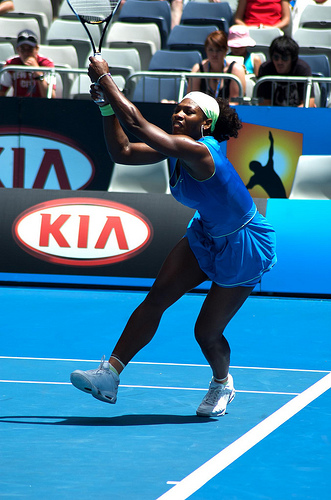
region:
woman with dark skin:
[61, 37, 292, 441]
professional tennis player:
[70, 41, 281, 432]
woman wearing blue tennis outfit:
[65, 44, 295, 444]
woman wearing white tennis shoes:
[60, 49, 282, 421]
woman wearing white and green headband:
[55, 29, 274, 445]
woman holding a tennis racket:
[59, 20, 271, 425]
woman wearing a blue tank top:
[66, 38, 280, 423]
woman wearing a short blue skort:
[55, 50, 283, 427]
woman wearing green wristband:
[68, 39, 285, 432]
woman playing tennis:
[47, 42, 293, 446]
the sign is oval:
[11, 195, 157, 268]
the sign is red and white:
[8, 194, 154, 269]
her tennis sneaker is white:
[71, 362, 124, 405]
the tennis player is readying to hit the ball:
[49, 0, 284, 426]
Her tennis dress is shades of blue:
[140, 134, 291, 300]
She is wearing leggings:
[102, 228, 252, 379]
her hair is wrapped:
[178, 85, 226, 137]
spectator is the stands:
[186, 29, 245, 103]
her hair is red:
[202, 29, 231, 64]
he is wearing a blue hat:
[15, 29, 39, 54]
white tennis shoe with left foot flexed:
[61, 351, 170, 431]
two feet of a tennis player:
[46, 343, 249, 422]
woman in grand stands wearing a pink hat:
[229, 25, 256, 97]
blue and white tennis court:
[0, 109, 299, 479]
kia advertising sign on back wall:
[2, 186, 329, 266]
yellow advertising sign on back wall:
[241, 123, 291, 201]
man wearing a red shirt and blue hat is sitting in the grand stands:
[0, 26, 81, 94]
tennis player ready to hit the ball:
[63, 56, 306, 422]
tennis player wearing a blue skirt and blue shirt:
[70, 9, 280, 414]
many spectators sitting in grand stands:
[0, 0, 327, 104]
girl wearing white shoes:
[67, 353, 237, 418]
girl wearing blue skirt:
[67, 52, 277, 416]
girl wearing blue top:
[162, 136, 257, 231]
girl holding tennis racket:
[57, 0, 127, 105]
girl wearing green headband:
[166, 91, 238, 145]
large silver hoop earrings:
[199, 124, 209, 138]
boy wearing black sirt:
[255, 39, 315, 105]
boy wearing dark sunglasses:
[270, 54, 295, 65]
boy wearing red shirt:
[0, 31, 58, 98]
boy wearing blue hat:
[2, 33, 57, 97]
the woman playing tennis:
[66, 1, 278, 417]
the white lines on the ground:
[246, 331, 325, 428]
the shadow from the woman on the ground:
[4, 403, 215, 435]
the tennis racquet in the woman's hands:
[65, 0, 132, 105]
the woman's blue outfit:
[162, 137, 279, 284]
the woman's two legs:
[67, 218, 253, 424]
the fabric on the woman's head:
[179, 87, 220, 131]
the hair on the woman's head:
[203, 91, 242, 145]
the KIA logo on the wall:
[9, 195, 158, 267]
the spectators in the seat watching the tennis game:
[3, 1, 330, 105]